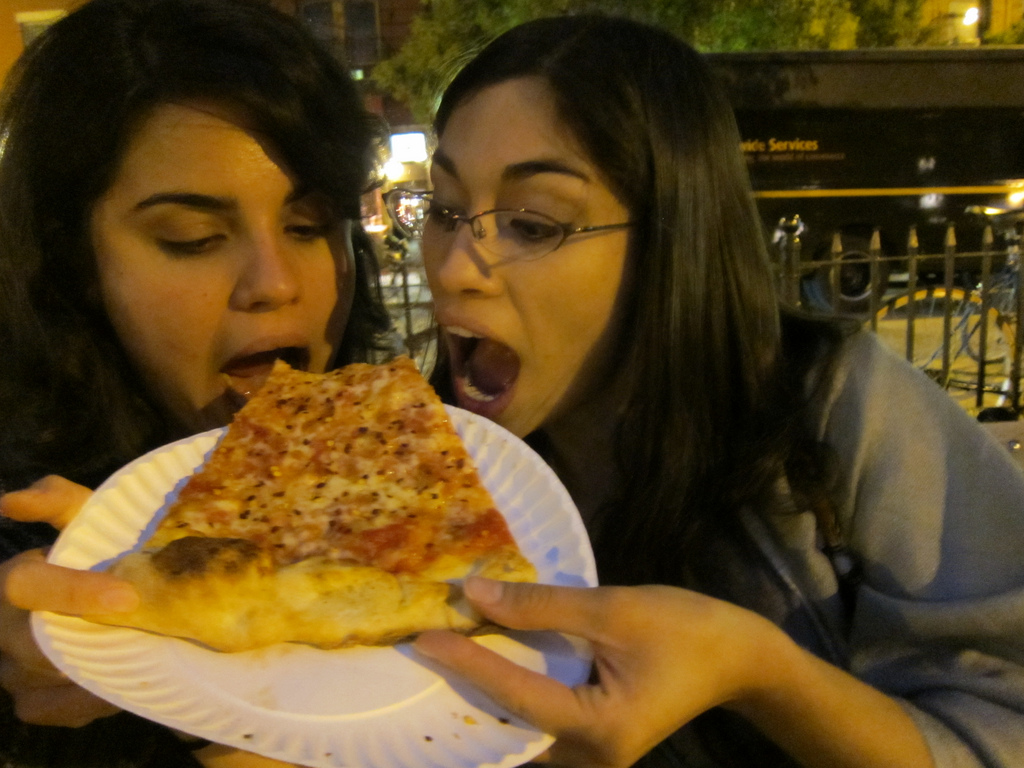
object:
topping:
[160, 534, 259, 577]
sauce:
[358, 523, 408, 545]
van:
[690, 50, 1024, 315]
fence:
[781, 218, 1024, 419]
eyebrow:
[133, 191, 226, 210]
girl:
[0, 0, 373, 763]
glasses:
[385, 189, 640, 262]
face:
[420, 100, 587, 438]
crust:
[86, 564, 537, 654]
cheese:
[316, 469, 417, 515]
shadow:
[501, 630, 575, 657]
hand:
[411, 579, 742, 767]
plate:
[32, 398, 603, 766]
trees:
[369, 4, 803, 122]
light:
[391, 133, 426, 163]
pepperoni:
[432, 493, 438, 498]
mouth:
[435, 311, 519, 419]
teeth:
[446, 326, 486, 337]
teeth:
[462, 376, 494, 401]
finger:
[411, 629, 578, 740]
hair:
[432, 23, 782, 584]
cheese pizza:
[100, 358, 532, 647]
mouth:
[220, 333, 311, 407]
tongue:
[470, 340, 518, 392]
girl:
[418, 19, 1023, 763]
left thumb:
[464, 575, 610, 645]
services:
[769, 138, 817, 151]